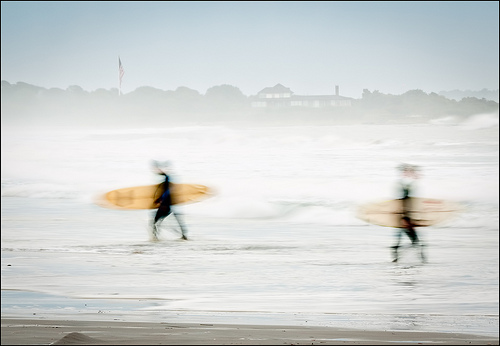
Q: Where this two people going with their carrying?
A: Playing surfboarding.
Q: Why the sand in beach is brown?
A: An normal color of the sand.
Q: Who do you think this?
A: A person.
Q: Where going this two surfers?
A: To take rest.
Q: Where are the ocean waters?
A: On the beach.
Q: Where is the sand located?
A: On the beach.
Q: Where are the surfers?
A: On the beach.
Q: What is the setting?
A: A beach.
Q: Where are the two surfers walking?
A: On the beach.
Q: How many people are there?
A: Two.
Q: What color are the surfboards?
A: Yellow and white.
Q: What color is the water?
A: Gray and white.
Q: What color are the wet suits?
A: Black.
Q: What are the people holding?
A: Surfboards.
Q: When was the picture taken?
A: Daytime.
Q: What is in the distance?
A: A flag.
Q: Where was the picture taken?
A: Ocean.